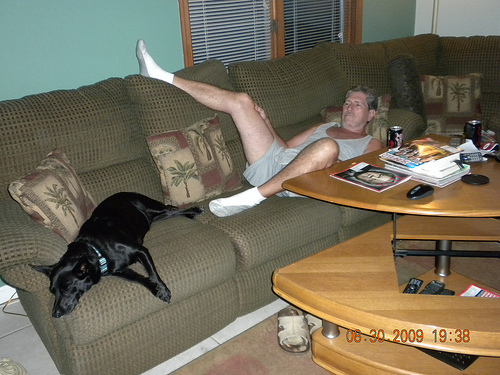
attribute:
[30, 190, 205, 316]
dog — sleeping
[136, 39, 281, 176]
leg — propped up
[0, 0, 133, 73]
wall — mint green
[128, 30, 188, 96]
foot — man's